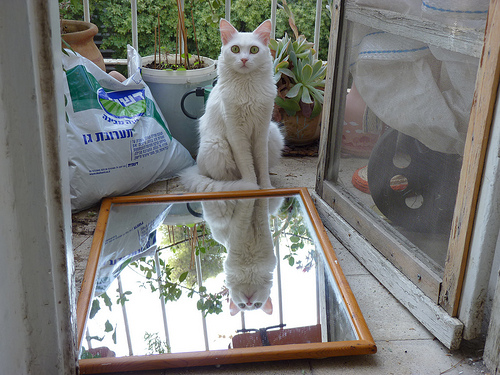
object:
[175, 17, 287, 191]
cat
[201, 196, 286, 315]
cat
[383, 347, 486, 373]
floor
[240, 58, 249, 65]
nose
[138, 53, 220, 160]
bucket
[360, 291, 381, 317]
ground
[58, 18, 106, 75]
pot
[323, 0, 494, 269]
screen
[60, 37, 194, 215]
bag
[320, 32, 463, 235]
reflection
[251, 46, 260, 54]
eyes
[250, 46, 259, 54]
eye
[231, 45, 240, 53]
eye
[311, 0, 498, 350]
door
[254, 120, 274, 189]
cat legs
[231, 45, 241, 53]
eyes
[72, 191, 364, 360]
mirror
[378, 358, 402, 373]
ground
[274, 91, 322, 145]
pot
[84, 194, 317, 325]
reflection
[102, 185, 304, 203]
frame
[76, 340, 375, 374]
frame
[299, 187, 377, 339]
frame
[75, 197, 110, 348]
frame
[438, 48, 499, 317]
frame